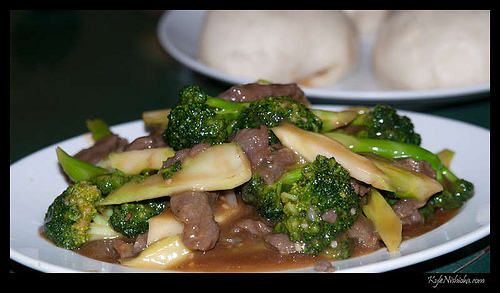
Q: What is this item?
A: A beef dish.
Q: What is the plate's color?
A: White.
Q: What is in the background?
A: Dumplings.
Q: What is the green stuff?
A: Broccoli.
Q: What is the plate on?
A: Table.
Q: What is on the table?
A: Plate.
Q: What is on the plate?
A: Food.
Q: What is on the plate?
A: Broccoli.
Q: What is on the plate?
A: Beef.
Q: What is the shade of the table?
A: Black.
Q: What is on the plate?
A: Food.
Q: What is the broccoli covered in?
A: Sauce.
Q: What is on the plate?
A: Stir fry.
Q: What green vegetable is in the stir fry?
A: Broccoli.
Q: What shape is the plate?
A: Circle.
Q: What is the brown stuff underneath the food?
A: Sauce.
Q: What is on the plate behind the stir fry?
A: Dumplings.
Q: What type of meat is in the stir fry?
A: Beef.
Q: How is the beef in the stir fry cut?
A: Into strips.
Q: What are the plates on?
A: A table.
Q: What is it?
A: Food.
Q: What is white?
A: The plate.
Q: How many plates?
A: 2.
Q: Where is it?
A: Table.